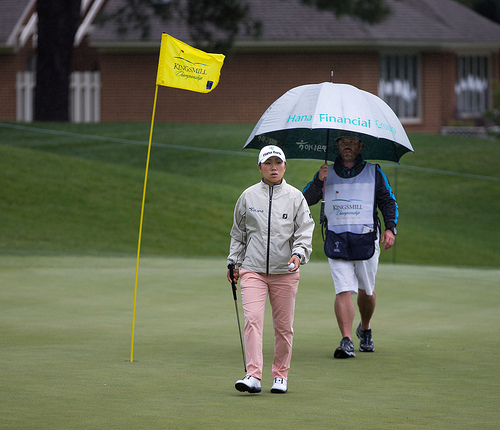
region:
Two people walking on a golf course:
[1, 24, 498, 427]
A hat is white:
[252, 141, 290, 169]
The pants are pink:
[232, 265, 304, 381]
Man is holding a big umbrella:
[241, 70, 402, 362]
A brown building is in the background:
[1, 0, 498, 133]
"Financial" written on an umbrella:
[314, 110, 374, 133]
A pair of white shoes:
[233, 368, 293, 400]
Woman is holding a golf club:
[223, 140, 315, 397]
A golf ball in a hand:
[283, 252, 303, 277]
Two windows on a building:
[372, 45, 495, 125]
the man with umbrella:
[236, 34, 404, 351]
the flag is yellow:
[77, 2, 222, 369]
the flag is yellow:
[120, 19, 244, 126]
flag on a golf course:
[116, 26, 235, 381]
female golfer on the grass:
[216, 137, 323, 402]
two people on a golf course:
[217, 73, 430, 393]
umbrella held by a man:
[246, 79, 416, 166]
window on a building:
[374, 51, 434, 134]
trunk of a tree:
[26, 3, 89, 121]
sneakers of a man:
[330, 323, 390, 363]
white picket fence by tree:
[75, 63, 103, 126]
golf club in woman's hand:
[218, 253, 257, 391]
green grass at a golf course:
[17, 147, 119, 238]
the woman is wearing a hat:
[257, 143, 284, 168]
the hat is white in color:
[257, 143, 284, 163]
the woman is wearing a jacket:
[228, 178, 314, 276]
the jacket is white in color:
[226, 177, 314, 277]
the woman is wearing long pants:
[237, 265, 304, 382]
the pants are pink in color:
[235, 266, 300, 381]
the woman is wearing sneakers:
[234, 373, 289, 393]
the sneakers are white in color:
[234, 373, 288, 394]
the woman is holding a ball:
[287, 255, 302, 272]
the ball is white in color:
[286, 260, 296, 270]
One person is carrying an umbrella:
[22, 30, 459, 420]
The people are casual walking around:
[30, 20, 465, 412]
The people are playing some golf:
[20, 25, 470, 406]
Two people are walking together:
[25, 15, 470, 410]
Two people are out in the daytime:
[17, 40, 472, 428]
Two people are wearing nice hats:
[36, 40, 458, 417]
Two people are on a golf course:
[35, 21, 453, 388]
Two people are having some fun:
[52, 35, 467, 411]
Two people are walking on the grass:
[57, 30, 452, 410]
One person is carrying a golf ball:
[36, 24, 465, 408]